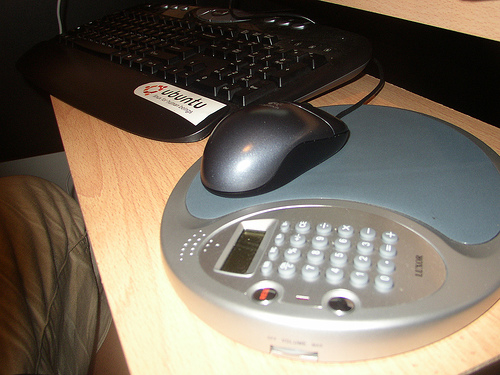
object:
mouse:
[200, 99, 350, 197]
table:
[37, 74, 499, 374]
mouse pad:
[184, 104, 499, 246]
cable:
[333, 61, 386, 118]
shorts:
[4, 176, 112, 373]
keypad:
[260, 220, 398, 291]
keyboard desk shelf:
[51, 74, 497, 374]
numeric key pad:
[196, 53, 299, 108]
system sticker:
[134, 82, 229, 125]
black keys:
[233, 79, 277, 107]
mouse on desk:
[180, 89, 396, 210]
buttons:
[351, 270, 366, 287]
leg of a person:
[2, 174, 111, 373]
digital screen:
[216, 227, 265, 273]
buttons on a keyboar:
[270, 58, 293, 71]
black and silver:
[267, 140, 302, 163]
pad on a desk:
[96, 93, 497, 347]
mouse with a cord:
[199, 58, 384, 196]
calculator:
[200, 204, 446, 313]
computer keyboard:
[18, 0, 373, 142]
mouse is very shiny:
[230, 155, 259, 175]